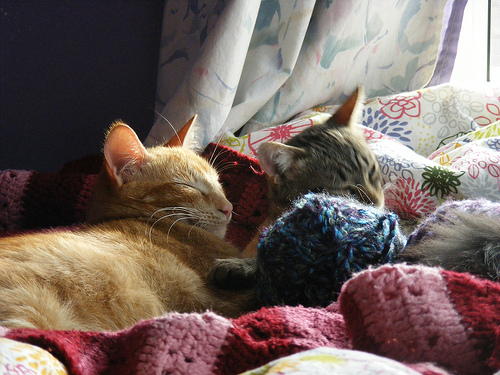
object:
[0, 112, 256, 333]
cat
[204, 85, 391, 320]
cat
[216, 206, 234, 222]
nose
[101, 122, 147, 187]
ear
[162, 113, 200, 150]
ear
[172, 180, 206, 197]
eye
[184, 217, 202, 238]
whisker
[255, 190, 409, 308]
yarn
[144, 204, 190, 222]
whisker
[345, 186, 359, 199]
eye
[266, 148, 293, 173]
hair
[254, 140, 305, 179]
ear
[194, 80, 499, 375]
blanket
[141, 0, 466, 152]
curtain